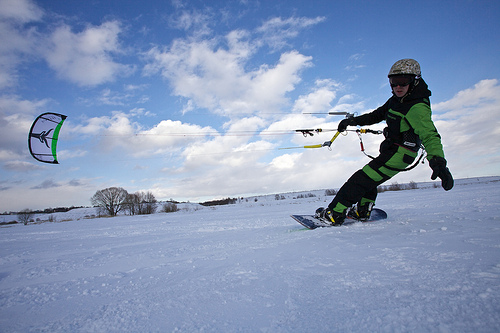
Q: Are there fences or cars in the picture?
A: No, there are no cars or fences.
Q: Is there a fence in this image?
A: No, there are no fences.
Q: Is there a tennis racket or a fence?
A: No, there are no fences or rackets.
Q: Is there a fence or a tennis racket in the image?
A: No, there are no fences or rackets.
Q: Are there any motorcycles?
A: No, there are no motorcycles.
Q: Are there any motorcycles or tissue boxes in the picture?
A: No, there are no motorcycles or tissue boxes.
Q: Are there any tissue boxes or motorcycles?
A: No, there are no motorcycles or tissue boxes.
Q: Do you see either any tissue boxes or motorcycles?
A: No, there are no motorcycles or tissue boxes.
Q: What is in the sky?
A: The clouds are in the sky.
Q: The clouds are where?
A: The clouds are in the sky.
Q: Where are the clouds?
A: The clouds are in the sky.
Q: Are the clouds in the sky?
A: Yes, the clouds are in the sky.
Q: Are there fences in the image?
A: No, there are no fences.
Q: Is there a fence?
A: No, there are no fences.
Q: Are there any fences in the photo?
A: No, there are no fences.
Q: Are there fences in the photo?
A: No, there are no fences.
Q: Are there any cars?
A: No, there are no cars.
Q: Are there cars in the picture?
A: No, there are no cars.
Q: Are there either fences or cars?
A: No, there are no cars or fences.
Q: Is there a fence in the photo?
A: No, there are no fences.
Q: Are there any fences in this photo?
A: No, there are no fences.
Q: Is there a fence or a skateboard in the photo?
A: No, there are no fences or skateboards.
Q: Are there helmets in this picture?
A: Yes, there is a helmet.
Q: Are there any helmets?
A: Yes, there is a helmet.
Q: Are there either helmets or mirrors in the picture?
A: Yes, there is a helmet.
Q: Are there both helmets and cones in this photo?
A: No, there is a helmet but no cones.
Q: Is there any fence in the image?
A: No, there are no fences.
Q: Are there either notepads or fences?
A: No, there are no fences or notepads.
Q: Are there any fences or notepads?
A: No, there are no fences or notepads.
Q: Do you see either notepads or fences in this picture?
A: No, there are no fences or notepads.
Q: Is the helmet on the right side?
A: Yes, the helmet is on the right of the image.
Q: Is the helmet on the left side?
A: No, the helmet is on the right of the image.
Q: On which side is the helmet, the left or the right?
A: The helmet is on the right of the image.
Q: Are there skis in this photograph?
A: No, there are no skis.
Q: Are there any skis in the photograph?
A: No, there are no skis.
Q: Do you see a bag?
A: No, there are no bags.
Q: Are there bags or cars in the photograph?
A: No, there are no bags or cars.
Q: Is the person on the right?
A: Yes, the person is on the right of the image.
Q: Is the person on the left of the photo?
A: No, the person is on the right of the image.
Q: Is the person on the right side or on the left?
A: The person is on the right of the image.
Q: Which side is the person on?
A: The person is on the right of the image.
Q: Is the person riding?
A: Yes, the person is riding.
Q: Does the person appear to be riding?
A: Yes, the person is riding.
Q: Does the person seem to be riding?
A: Yes, the person is riding.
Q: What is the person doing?
A: The person is riding.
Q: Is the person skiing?
A: No, the person is riding.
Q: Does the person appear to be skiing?
A: No, the person is riding.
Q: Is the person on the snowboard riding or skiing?
A: The person is riding.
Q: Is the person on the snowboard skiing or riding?
A: The person is riding.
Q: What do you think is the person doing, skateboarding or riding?
A: The person is riding.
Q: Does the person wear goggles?
A: Yes, the person wears goggles.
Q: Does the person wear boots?
A: No, the person wears goggles.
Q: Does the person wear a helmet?
A: Yes, the person wears a helmet.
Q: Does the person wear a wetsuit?
A: No, the person wears a helmet.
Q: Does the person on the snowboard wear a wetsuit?
A: No, the person wears a helmet.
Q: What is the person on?
A: The person is on the snowboard.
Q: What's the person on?
A: The person is on the snowboard.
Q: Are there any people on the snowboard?
A: Yes, there is a person on the snowboard.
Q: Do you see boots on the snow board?
A: No, there is a person on the snow board.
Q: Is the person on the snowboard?
A: Yes, the person is on the snowboard.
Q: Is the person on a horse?
A: No, the person is on the snowboard.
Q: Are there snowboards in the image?
A: Yes, there is a snowboard.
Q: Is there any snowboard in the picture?
A: Yes, there is a snowboard.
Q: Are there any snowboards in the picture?
A: Yes, there is a snowboard.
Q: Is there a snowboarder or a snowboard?
A: Yes, there is a snowboard.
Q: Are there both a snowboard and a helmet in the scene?
A: Yes, there are both a snowboard and a helmet.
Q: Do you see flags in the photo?
A: No, there are no flags.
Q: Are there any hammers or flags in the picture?
A: No, there are no flags or hammers.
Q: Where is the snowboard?
A: The snowboard is on the ground.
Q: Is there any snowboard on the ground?
A: Yes, there is a snowboard on the ground.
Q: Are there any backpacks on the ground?
A: No, there is a snowboard on the ground.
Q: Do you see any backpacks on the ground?
A: No, there is a snowboard on the ground.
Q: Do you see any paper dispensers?
A: No, there are no paper dispensers.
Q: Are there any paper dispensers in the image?
A: No, there are no paper dispensers.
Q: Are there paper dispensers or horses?
A: No, there are no paper dispensers or horses.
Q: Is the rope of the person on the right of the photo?
A: Yes, the rope is on the right of the image.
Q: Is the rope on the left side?
A: No, the rope is on the right of the image.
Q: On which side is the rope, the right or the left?
A: The rope is on the right of the image.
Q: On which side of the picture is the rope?
A: The rope is on the right of the image.